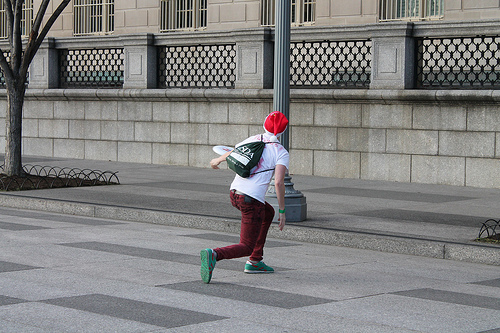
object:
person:
[194, 107, 293, 281]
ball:
[266, 133, 279, 143]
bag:
[224, 127, 286, 178]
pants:
[195, 179, 289, 279]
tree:
[0, 0, 64, 185]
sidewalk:
[0, 143, 500, 264]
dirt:
[0, 173, 119, 194]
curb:
[0, 189, 500, 265]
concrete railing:
[0, 22, 500, 89]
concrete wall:
[0, 87, 500, 188]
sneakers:
[198, 249, 226, 283]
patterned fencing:
[0, 22, 500, 188]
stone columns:
[228, 28, 272, 88]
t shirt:
[224, 123, 288, 210]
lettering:
[234, 143, 270, 167]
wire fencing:
[1, 162, 124, 183]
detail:
[123, 46, 147, 76]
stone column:
[121, 33, 151, 94]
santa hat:
[261, 109, 290, 139]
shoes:
[244, 251, 275, 278]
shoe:
[200, 251, 227, 282]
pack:
[223, 140, 297, 178]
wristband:
[278, 207, 290, 214]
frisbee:
[211, 140, 240, 157]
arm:
[272, 152, 290, 214]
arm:
[220, 139, 256, 160]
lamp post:
[262, 0, 292, 181]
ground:
[0, 149, 500, 332]